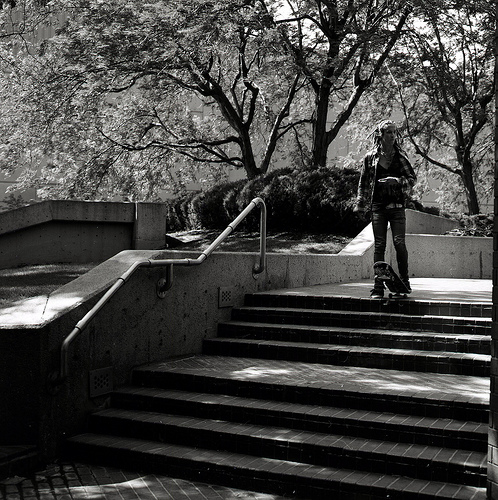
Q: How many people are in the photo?
A: One.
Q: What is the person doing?
A: Skateboarding.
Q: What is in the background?
A: Trees.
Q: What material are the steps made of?
A: Brick.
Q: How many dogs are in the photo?
A: None.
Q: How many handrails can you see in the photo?
A: 1.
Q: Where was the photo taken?
A: At a stairway.